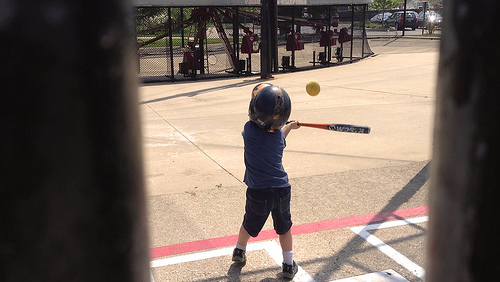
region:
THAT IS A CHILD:
[225, 89, 315, 269]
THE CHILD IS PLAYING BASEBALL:
[218, 87, 342, 264]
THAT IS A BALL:
[303, 72, 330, 107]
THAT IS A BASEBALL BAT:
[282, 119, 369, 142]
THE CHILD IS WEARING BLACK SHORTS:
[249, 187, 293, 225]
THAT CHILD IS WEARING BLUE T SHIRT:
[243, 132, 289, 180]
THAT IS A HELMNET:
[244, 70, 296, 125]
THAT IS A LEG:
[280, 204, 295, 279]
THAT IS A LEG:
[236, 194, 262, 272]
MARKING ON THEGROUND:
[332, 203, 354, 236]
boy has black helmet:
[232, 54, 294, 136]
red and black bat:
[293, 111, 358, 134]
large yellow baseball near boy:
[295, 82, 322, 98]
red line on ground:
[130, 218, 427, 263]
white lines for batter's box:
[137, 218, 452, 280]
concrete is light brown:
[285, 94, 418, 244]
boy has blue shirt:
[237, 120, 301, 202]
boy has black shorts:
[252, 175, 294, 240]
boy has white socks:
[276, 247, 299, 268]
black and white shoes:
[277, 247, 299, 274]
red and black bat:
[260, 96, 380, 131]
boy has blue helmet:
[249, 75, 277, 138]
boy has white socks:
[287, 242, 308, 272]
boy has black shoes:
[278, 252, 300, 279]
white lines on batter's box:
[170, 235, 306, 278]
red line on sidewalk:
[127, 210, 412, 240]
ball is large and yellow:
[276, 70, 324, 102]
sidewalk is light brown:
[269, 70, 387, 175]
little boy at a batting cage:
[227, 73, 380, 280]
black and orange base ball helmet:
[244, 81, 292, 131]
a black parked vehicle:
[379, 8, 419, 30]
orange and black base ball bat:
[288, 114, 373, 135]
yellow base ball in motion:
[304, 78, 320, 95]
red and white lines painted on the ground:
[133, 198, 433, 280]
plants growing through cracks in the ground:
[186, 176, 228, 199]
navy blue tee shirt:
[235, 115, 292, 188]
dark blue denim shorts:
[234, 180, 297, 240]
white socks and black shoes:
[275, 245, 301, 276]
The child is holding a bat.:
[244, 69, 336, 276]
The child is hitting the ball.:
[213, 51, 390, 181]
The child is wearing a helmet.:
[242, 88, 295, 118]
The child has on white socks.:
[278, 245, 303, 262]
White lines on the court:
[338, 212, 418, 277]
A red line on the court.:
[306, 205, 426, 230]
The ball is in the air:
[293, 69, 340, 104]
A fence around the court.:
[147, 13, 354, 97]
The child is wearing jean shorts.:
[236, 180, 295, 229]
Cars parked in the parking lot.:
[375, 5, 434, 40]